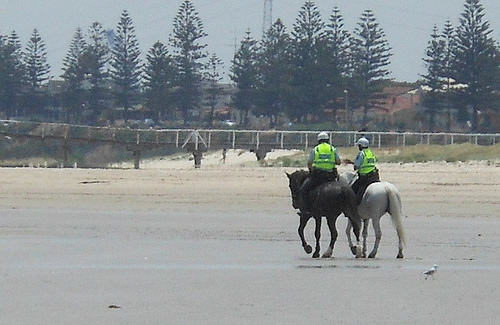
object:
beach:
[0, 165, 498, 325]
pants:
[298, 169, 340, 209]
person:
[350, 137, 380, 195]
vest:
[311, 142, 337, 172]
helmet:
[356, 138, 369, 148]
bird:
[420, 264, 438, 281]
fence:
[0, 119, 500, 151]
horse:
[284, 168, 364, 258]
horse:
[336, 171, 407, 259]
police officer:
[298, 131, 342, 216]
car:
[218, 119, 238, 126]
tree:
[165, 1, 210, 129]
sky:
[0, 0, 500, 86]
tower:
[262, 0, 273, 46]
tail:
[341, 185, 362, 239]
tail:
[385, 186, 406, 249]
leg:
[326, 214, 339, 250]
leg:
[372, 215, 383, 253]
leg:
[297, 213, 313, 246]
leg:
[345, 220, 354, 244]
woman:
[218, 147, 229, 164]